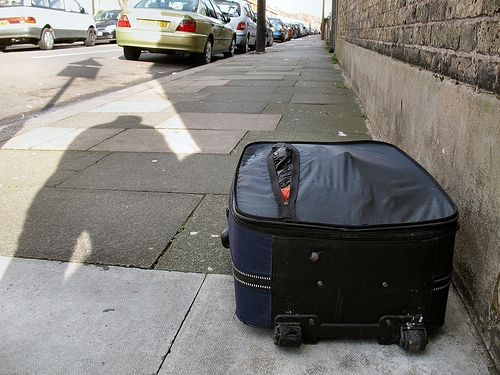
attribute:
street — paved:
[23, 52, 110, 92]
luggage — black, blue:
[199, 84, 473, 367]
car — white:
[211, 0, 266, 52]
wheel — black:
[402, 322, 430, 353]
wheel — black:
[273, 322, 300, 347]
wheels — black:
[269, 307, 444, 374]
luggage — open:
[201, 112, 478, 337]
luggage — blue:
[174, 93, 440, 349]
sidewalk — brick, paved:
[0, 35, 496, 373]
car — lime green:
[112, 0, 239, 67]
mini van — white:
[1, 0, 99, 55]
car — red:
[283, 21, 295, 39]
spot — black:
[99, 305, 116, 315]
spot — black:
[98, 258, 114, 272]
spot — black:
[330, 351, 362, 370]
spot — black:
[299, 358, 323, 373]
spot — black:
[113, 134, 130, 144]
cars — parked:
[115, 1, 317, 56]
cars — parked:
[1, 1, 115, 48]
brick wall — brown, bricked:
[330, 0, 498, 90]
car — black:
[92, 11, 117, 43]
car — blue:
[267, 14, 295, 45]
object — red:
[278, 185, 292, 200]